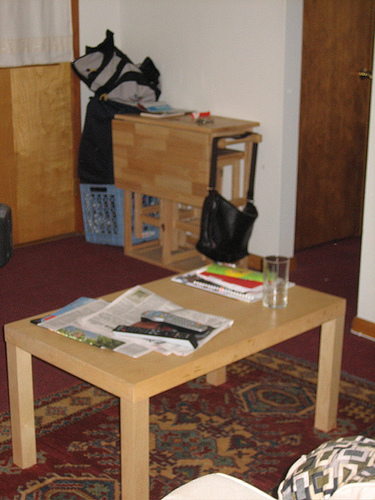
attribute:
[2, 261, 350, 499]
table — wooden, wood, woody, solid, ligneous, resembling wood, strong, sturdy, sound, tan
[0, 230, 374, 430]
carpet — red, reddish, shade of red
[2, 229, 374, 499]
floor — carpeted, covered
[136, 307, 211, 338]
remote — silver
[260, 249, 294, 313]
glass — empty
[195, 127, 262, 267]
purse — hanging, black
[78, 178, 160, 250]
basket — blue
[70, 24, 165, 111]
bag — gray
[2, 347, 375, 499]
rug — persian style, patterened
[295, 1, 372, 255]
door — wood, brown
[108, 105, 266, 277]
table — wood, folded, wooden, tan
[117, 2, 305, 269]
wall — white